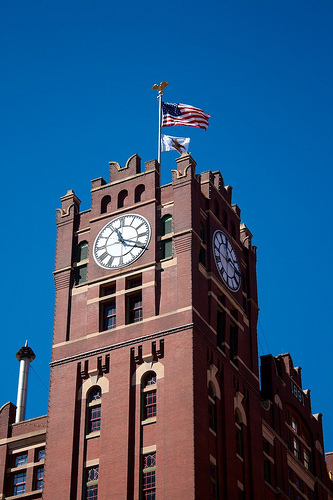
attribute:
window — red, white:
[34, 464, 46, 491]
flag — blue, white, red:
[156, 99, 214, 130]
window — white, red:
[136, 368, 162, 423]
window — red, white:
[80, 382, 99, 434]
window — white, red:
[82, 464, 99, 498]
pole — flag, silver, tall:
[153, 82, 168, 163]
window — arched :
[157, 210, 178, 262]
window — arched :
[74, 234, 94, 277]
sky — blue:
[177, 22, 298, 102]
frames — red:
[69, 200, 193, 326]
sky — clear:
[30, 30, 140, 97]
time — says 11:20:
[78, 194, 174, 274]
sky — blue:
[201, 50, 329, 88]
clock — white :
[91, 212, 152, 273]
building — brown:
[11, 143, 323, 490]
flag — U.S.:
[141, 93, 225, 140]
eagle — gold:
[135, 70, 176, 103]